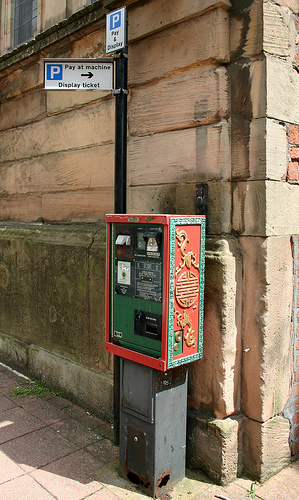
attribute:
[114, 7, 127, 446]
pole — metal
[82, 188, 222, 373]
box — metal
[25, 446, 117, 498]
tile — cement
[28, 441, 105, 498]
tile — cement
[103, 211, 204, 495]
machine — green and red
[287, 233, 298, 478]
wall — red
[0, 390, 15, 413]
square brick — red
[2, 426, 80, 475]
tile — cement